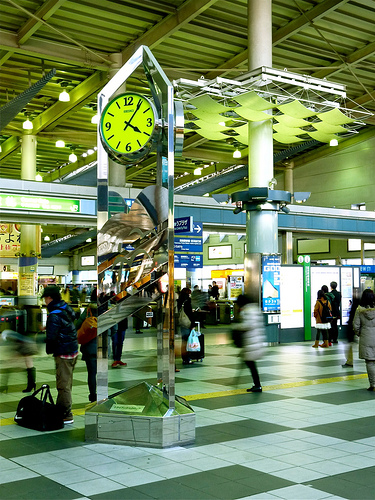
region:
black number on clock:
[121, 93, 134, 108]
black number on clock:
[143, 114, 153, 132]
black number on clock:
[122, 135, 133, 152]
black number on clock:
[102, 119, 115, 135]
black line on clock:
[137, 103, 150, 115]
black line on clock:
[140, 129, 152, 139]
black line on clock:
[133, 136, 144, 149]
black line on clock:
[113, 138, 125, 151]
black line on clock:
[104, 131, 116, 143]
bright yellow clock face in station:
[99, 86, 163, 159]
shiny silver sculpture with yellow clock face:
[81, 38, 203, 446]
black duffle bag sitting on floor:
[11, 380, 67, 439]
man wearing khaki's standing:
[38, 283, 90, 431]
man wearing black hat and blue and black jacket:
[36, 283, 87, 424]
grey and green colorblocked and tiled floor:
[2, 318, 365, 494]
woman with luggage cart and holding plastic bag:
[175, 282, 214, 367]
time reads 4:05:
[96, 88, 159, 164]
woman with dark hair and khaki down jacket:
[350, 287, 373, 392]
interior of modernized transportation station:
[0, 1, 370, 497]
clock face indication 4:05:
[95, 94, 160, 161]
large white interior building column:
[246, 45, 278, 328]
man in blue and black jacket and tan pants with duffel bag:
[13, 286, 76, 430]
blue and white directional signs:
[174, 216, 204, 267]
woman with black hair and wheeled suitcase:
[178, 287, 203, 365]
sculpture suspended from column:
[169, 76, 373, 148]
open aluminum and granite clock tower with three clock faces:
[85, 44, 195, 447]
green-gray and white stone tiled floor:
[0, 321, 374, 498]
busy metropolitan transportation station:
[2, 1, 373, 498]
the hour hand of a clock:
[122, 120, 141, 132]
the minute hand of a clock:
[120, 106, 144, 125]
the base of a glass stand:
[91, 387, 195, 437]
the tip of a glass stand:
[134, 39, 153, 56]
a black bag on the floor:
[18, 389, 61, 434]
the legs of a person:
[56, 364, 82, 431]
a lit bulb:
[57, 93, 70, 101]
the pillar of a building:
[245, 128, 285, 302]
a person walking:
[353, 290, 374, 359]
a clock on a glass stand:
[100, 93, 160, 154]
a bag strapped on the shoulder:
[180, 295, 195, 326]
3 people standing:
[313, 277, 344, 350]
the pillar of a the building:
[249, 132, 288, 260]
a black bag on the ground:
[14, 380, 62, 433]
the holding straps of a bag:
[32, 384, 55, 399]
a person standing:
[38, 287, 82, 427]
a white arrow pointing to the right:
[194, 223, 202, 234]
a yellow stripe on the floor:
[185, 383, 250, 406]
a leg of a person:
[245, 358, 266, 395]